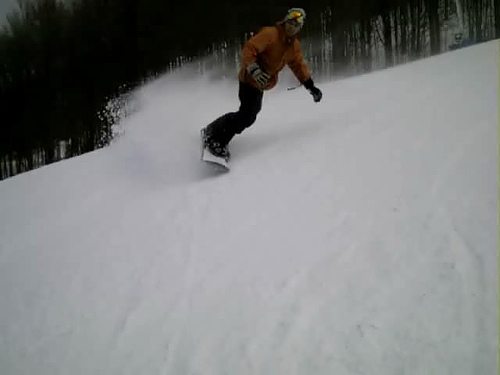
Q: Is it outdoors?
A: Yes, it is outdoors.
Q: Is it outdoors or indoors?
A: It is outdoors.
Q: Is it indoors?
A: No, it is outdoors.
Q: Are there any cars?
A: No, there are no cars.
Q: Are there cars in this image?
A: No, there are no cars.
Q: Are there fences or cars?
A: No, there are no cars or fences.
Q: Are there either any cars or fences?
A: No, there are no cars or fences.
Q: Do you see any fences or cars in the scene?
A: No, there are no cars or fences.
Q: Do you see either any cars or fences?
A: No, there are no cars or fences.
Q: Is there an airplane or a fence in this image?
A: No, there are no fences or airplanes.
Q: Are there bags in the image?
A: No, there are no bags.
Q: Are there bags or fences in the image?
A: No, there are no bags or fences.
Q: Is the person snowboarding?
A: Yes, the person is snowboarding.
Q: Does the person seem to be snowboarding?
A: Yes, the person is snowboarding.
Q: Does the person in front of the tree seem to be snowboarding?
A: Yes, the person is snowboarding.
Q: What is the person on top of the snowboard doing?
A: The person is snowboarding.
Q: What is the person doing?
A: The person is snowboarding.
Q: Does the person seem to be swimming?
A: No, the person is snowboarding.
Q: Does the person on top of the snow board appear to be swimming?
A: No, the person is snowboarding.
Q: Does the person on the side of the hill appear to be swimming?
A: No, the person is snowboarding.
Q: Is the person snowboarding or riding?
A: The person is snowboarding.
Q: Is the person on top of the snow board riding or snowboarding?
A: The person is snowboarding.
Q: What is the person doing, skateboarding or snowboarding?
A: The person is snowboarding.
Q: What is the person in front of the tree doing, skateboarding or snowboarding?
A: The person is snowboarding.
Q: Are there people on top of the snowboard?
A: Yes, there is a person on top of the snowboard.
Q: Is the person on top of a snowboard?
A: Yes, the person is on top of a snowboard.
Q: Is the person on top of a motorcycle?
A: No, the person is on top of a snowboard.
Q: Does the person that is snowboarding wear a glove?
A: Yes, the person wears a glove.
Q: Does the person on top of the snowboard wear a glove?
A: Yes, the person wears a glove.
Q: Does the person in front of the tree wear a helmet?
A: No, the person wears a glove.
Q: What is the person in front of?
A: The person is in front of the tree.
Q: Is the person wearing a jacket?
A: Yes, the person is wearing a jacket.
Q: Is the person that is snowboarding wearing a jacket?
A: Yes, the person is wearing a jacket.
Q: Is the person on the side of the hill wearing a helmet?
A: No, the person is wearing a jacket.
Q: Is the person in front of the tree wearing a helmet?
A: No, the person is wearing a jacket.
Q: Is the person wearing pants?
A: Yes, the person is wearing pants.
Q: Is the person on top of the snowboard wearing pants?
A: Yes, the person is wearing pants.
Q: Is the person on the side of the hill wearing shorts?
A: No, the person is wearing pants.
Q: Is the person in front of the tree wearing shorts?
A: No, the person is wearing pants.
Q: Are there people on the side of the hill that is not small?
A: Yes, there is a person on the side of the hill.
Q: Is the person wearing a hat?
A: Yes, the person is wearing a hat.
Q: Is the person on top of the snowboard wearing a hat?
A: Yes, the person is wearing a hat.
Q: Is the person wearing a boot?
A: No, the person is wearing a hat.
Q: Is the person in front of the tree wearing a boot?
A: No, the person is wearing a hat.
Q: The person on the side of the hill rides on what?
A: The person rides on the snowboard.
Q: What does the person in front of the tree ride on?
A: The person rides on the snowboard.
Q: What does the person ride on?
A: The person rides on the snowboard.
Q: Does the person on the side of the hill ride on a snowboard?
A: Yes, the person rides on a snowboard.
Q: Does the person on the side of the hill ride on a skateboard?
A: No, the person rides on a snowboard.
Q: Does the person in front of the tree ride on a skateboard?
A: No, the person rides on a snowboard.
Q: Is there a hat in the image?
A: Yes, there is a hat.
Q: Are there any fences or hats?
A: Yes, there is a hat.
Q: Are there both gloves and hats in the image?
A: Yes, there are both a hat and gloves.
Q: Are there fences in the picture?
A: No, there are no fences.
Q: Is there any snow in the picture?
A: Yes, there is snow.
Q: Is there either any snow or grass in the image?
A: Yes, there is snow.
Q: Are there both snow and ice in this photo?
A: No, there is snow but no ice.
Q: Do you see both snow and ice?
A: No, there is snow but no ice.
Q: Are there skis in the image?
A: No, there are no skis.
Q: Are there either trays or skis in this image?
A: No, there are no skis or trays.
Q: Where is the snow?
A: The snow is on the hill.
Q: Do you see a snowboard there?
A: Yes, there is a snowboard.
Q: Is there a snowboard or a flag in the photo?
A: Yes, there is a snowboard.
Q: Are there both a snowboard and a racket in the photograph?
A: No, there is a snowboard but no rackets.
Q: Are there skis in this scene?
A: No, there are no skis.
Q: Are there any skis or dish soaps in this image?
A: No, there are no skis or dish soaps.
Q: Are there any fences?
A: No, there are no fences.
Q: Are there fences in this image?
A: No, there are no fences.